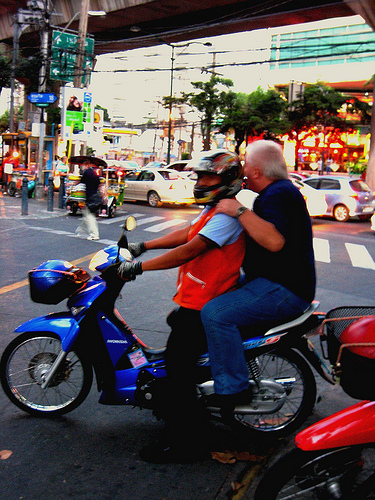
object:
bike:
[0, 214, 329, 440]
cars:
[121, 168, 197, 207]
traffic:
[50, 154, 372, 219]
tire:
[1, 327, 97, 417]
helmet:
[192, 148, 245, 202]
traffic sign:
[27, 93, 57, 104]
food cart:
[63, 156, 123, 216]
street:
[0, 50, 373, 198]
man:
[202, 139, 316, 407]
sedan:
[303, 173, 375, 221]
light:
[204, 41, 213, 49]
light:
[85, 8, 105, 18]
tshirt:
[246, 179, 318, 299]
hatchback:
[298, 175, 374, 223]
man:
[74, 160, 103, 240]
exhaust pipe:
[274, 377, 295, 386]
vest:
[170, 208, 244, 310]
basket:
[28, 258, 76, 304]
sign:
[50, 29, 96, 55]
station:
[99, 127, 140, 157]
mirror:
[126, 215, 137, 233]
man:
[119, 150, 246, 463]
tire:
[220, 344, 318, 444]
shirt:
[182, 200, 241, 250]